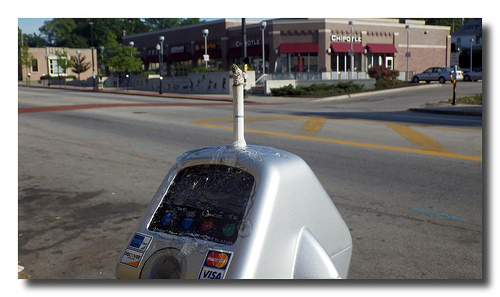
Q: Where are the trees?
A: Sidewalk.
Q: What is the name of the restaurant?
A: Chipotle.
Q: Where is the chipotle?
A: Shopping plaza.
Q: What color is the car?
A: Silver.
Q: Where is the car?
A: The parking lot.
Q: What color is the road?
A: Gray.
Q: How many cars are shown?
A: One.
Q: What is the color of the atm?
A: Silver.